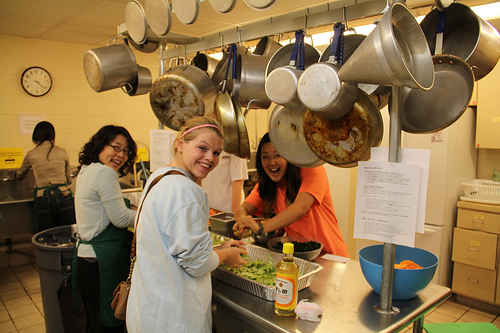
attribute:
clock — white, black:
[22, 65, 52, 95]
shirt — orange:
[244, 165, 350, 257]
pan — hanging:
[329, 3, 439, 103]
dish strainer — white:
[464, 175, 498, 198]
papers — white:
[319, 104, 453, 287]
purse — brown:
[114, 219, 128, 324]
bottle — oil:
[275, 242, 299, 318]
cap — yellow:
[284, 240, 294, 254]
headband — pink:
[175, 121, 232, 138]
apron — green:
[60, 181, 134, 324]